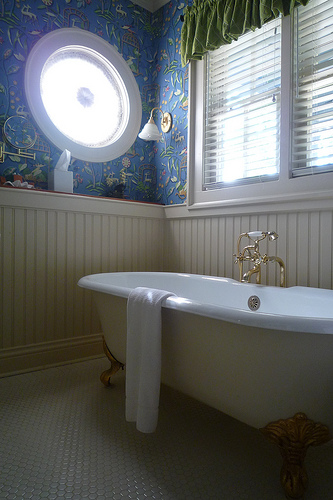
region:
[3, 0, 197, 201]
blue decorated wallpaper on wall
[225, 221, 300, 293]
golden tap and shower head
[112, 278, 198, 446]
towel hanging on side of bathtub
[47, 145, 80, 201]
box of white tissues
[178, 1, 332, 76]
green valence curtain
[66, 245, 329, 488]
bathtub is sitting on floor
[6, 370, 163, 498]
white tiles on floor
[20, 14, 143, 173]
window is round and let's the light in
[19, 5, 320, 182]
picture taken in daylight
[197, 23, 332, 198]
white blinds on window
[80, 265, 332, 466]
the white claw tub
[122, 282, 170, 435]
the white towel on the tub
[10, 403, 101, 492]
the hexagon tiled floor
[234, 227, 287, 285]
the gold tub fixtures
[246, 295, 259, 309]
the drain on the tub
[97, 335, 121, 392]
the gold foot claws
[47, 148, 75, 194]
the white tissue paper holder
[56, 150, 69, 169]
the white tissue paper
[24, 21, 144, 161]
the small circle window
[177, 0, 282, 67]
the green valance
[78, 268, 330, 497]
a big bath tub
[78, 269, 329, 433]
the bath tub is white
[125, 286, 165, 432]
this is a white towel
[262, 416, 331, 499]
a golden stand for the tub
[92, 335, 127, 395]
a golden stand for the tub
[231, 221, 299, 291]
the taps are golden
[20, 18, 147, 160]
a round wall mirror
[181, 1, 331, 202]
this is a wondow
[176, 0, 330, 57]
the curtains are green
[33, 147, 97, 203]
a box paper towels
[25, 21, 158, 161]
a round window with light pouring in.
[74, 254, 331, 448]
a very large white bath tub.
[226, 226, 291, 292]
golden bathtub water faucet.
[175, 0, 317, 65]
a green bathroom curtain.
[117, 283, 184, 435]
a white towel on a bath tub.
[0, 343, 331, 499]
a tiled bathroom floor.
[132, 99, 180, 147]
a light on a bathroom wall.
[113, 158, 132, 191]
a drawing on wall paper.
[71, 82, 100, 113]
the center of a bathroom window.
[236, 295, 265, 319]
overflow drain on a bath tub.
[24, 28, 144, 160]
a circle shaped window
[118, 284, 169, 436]
a white hanging bath towel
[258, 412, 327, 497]
a brass claw tub foot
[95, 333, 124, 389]
a brass claw tub foot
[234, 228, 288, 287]
a brass bathtub faucet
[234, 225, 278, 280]
a brass bathtub shower head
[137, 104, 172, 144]
a wall light and shade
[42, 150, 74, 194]
a white box of facial tissue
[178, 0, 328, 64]
a green curtain top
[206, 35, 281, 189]
opened white venetian blinds